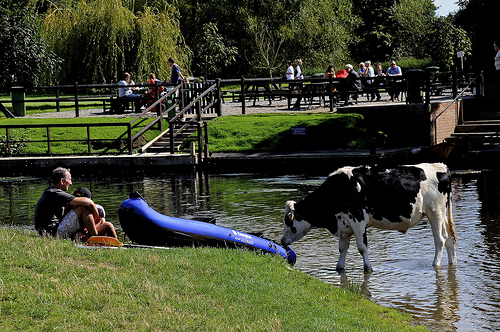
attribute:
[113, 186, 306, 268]
raft — blue, inflatable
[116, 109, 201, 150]
stairway — wooden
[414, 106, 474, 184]
wall — black, yellow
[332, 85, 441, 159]
wall — brick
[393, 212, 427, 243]
ground — wooden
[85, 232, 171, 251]
oar — brown, black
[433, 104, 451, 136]
wall — brick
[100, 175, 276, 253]
raft — blue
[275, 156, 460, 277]
cow — black, white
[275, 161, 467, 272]
cow — black, white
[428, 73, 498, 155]
stairway — metal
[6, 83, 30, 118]
trash can — green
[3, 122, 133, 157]
fence — wooden